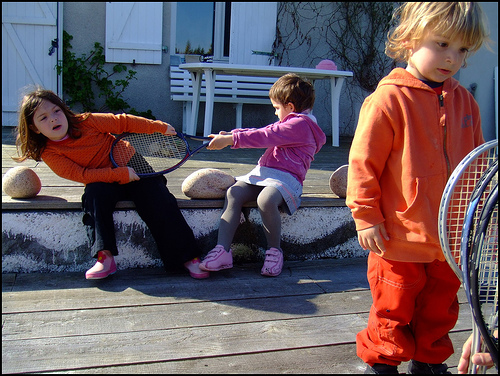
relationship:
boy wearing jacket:
[350, 0, 497, 375] [344, 74, 494, 263]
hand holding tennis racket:
[461, 320, 499, 375] [435, 138, 499, 285]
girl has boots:
[203, 75, 324, 274] [198, 240, 300, 283]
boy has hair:
[350, 0, 497, 375] [379, 6, 494, 54]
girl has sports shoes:
[24, 93, 206, 278] [71, 241, 210, 291]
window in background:
[163, 4, 223, 63] [7, 6, 500, 157]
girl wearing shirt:
[24, 93, 206, 278] [37, 108, 166, 191]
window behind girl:
[163, 4, 223, 63] [24, 93, 206, 278]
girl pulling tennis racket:
[24, 93, 206, 278] [110, 125, 210, 177]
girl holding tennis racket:
[203, 75, 324, 274] [110, 125, 210, 177]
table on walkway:
[169, 62, 351, 149] [1, 126, 496, 376]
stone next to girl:
[180, 170, 244, 204] [203, 75, 324, 274]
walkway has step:
[1, 126, 496, 376] [0, 190, 500, 276]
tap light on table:
[305, 55, 342, 78] [169, 62, 351, 149]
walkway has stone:
[1, 126, 496, 376] [180, 170, 244, 204]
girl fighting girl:
[24, 93, 206, 278] [203, 75, 324, 274]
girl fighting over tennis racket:
[24, 93, 206, 278] [110, 125, 210, 177]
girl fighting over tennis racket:
[203, 75, 324, 274] [110, 125, 210, 177]